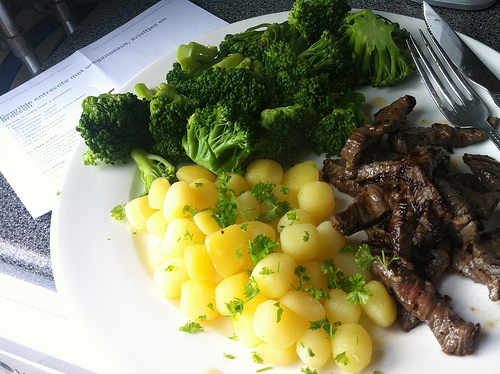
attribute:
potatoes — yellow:
[176, 210, 388, 367]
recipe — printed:
[3, 0, 230, 219]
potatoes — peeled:
[127, 161, 392, 369]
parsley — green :
[244, 277, 262, 307]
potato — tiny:
[250, 248, 300, 301]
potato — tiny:
[296, 178, 337, 218]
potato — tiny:
[358, 275, 398, 328]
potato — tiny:
[203, 220, 253, 279]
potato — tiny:
[250, 295, 314, 349]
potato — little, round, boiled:
[331, 320, 377, 372]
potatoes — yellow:
[142, 136, 390, 373]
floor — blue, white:
[0, 1, 96, 101]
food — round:
[121, 64, 466, 301]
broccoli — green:
[78, 2, 419, 178]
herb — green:
[243, 231, 286, 271]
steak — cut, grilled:
[310, 103, 498, 361]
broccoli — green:
[56, 2, 414, 157]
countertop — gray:
[7, 5, 262, 271]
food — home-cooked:
[145, 53, 472, 346]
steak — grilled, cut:
[313, 100, 498, 325]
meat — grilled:
[318, 94, 498, 355]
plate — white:
[57, 212, 112, 289]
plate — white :
[36, 9, 484, 365]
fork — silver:
[399, 29, 483, 144]